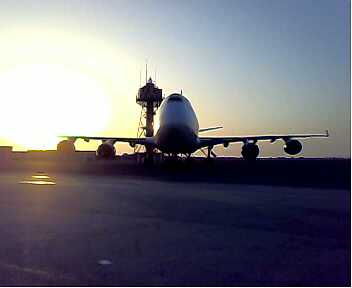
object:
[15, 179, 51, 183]
reflection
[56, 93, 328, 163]
aircraft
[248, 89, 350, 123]
side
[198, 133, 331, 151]
wing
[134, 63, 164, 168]
tower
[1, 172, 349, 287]
grounds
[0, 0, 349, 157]
sky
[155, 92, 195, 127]
compartment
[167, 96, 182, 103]
window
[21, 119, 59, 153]
sun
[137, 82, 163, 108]
transformer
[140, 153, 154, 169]
wheel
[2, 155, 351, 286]
tarmac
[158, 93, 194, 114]
head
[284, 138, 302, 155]
propeller